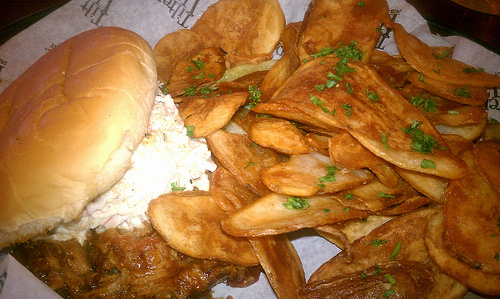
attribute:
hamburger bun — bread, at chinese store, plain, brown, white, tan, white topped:
[10, 65, 131, 151]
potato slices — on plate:
[265, 114, 412, 276]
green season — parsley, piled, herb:
[318, 43, 387, 102]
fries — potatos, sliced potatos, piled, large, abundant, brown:
[201, 28, 300, 161]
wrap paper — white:
[149, 13, 170, 26]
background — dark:
[438, 7, 473, 30]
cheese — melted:
[154, 29, 211, 90]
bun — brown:
[2, 25, 153, 246]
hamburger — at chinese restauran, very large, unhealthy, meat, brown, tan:
[67, 224, 150, 296]